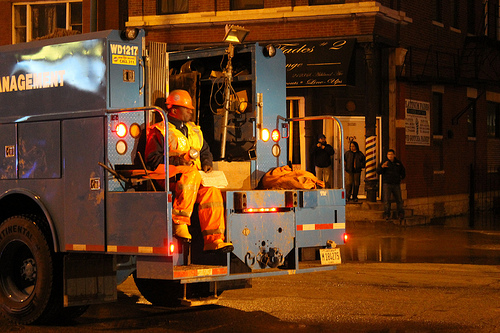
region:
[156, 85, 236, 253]
the man is sitting on the back of the truck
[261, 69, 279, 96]
the truck is light blue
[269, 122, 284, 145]
the light is on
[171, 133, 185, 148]
the vest is is orange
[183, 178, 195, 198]
the pants are orange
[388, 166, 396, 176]
the coat is black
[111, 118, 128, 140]
the light is red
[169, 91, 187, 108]
the hat is orange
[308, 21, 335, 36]
the building is made of bricks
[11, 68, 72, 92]
the ord is white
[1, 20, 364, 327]
a work truck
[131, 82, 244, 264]
man sitting on the back of the truck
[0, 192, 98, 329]
wheel of the truck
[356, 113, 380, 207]
red, white, and blue barber pole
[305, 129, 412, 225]
three people on the street corner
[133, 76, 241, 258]
man wearing a yellow suit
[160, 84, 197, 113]
orange hard hat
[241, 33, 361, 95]
sign for a barber shop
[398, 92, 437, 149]
square sign on the wall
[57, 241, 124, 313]
mud flap on the back of the truck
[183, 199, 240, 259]
worker on back of truck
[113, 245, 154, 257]
red and white stripe on the truck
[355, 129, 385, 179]
stripes on the pole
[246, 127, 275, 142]
lights are on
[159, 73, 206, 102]
worker is wearing a hard hat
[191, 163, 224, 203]
worker is holding papers in his hand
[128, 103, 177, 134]
bar on the back of truck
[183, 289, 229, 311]
step on the back of truck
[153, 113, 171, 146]
worker is wearing a safety vest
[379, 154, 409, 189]
man standing next to building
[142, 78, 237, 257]
A construction worker sitting on the back of a truck.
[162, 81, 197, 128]
An orange hardhat on a man.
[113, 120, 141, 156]
Taillights on a truck.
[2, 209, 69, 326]
The back tire on a truck.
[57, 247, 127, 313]
A mudflap on a truck.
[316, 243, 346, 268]
The license plate on a truck.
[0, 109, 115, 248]
Storage compartments on a work truck.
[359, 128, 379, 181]
A striped barbers pole outside a store.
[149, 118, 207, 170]
A yellow safety vest on a man.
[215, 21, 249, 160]
A portable light on the back of a truck.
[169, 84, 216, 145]
Man wearing orange hard hat.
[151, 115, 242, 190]
Man wearing orange vest.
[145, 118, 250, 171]
Man wearing dark long sleeve shirt.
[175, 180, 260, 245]
Man wearing orange pants.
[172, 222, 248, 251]
Man wearing orange shoes.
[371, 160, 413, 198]
Man wearing black coat.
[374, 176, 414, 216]
Man wearing blue jeans.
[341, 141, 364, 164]
Person wearing dark coat.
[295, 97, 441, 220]
3 people standing by corner of building.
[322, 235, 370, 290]
White license plate on truck.